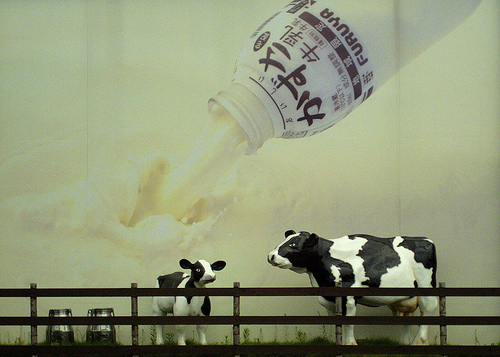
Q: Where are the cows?
A: On the advertisement.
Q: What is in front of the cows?
A: A fence.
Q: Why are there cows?
A: It is a milk advertisement.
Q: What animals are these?
A: Cows.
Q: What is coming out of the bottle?
A: Milk.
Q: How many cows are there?
A: Two.